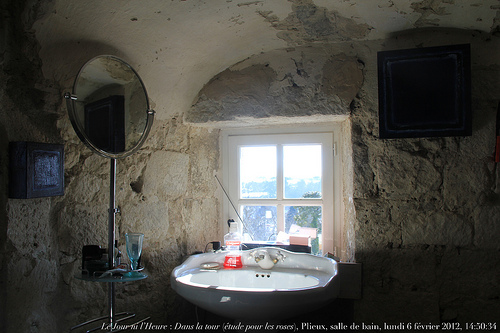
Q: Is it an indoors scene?
A: Yes, it is indoors.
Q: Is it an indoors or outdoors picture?
A: It is indoors.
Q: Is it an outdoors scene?
A: No, it is indoors.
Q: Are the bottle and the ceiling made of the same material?
A: No, the bottle is made of plastic and the ceiling is made of concrete.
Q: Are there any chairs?
A: No, there are no chairs.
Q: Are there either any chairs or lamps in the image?
A: No, there are no chairs or lamps.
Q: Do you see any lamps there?
A: No, there are no lamps.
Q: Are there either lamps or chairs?
A: No, there are no lamps or chairs.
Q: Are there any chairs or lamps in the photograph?
A: No, there are no lamps or chairs.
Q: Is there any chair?
A: No, there are no chairs.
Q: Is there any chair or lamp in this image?
A: No, there are no chairs or lamps.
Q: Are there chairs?
A: No, there are no chairs.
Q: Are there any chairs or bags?
A: No, there are no chairs or bags.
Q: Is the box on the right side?
A: Yes, the box is on the right of the image.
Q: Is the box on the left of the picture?
A: No, the box is on the right of the image.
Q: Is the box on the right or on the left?
A: The box is on the right of the image.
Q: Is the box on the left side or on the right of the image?
A: The box is on the right of the image.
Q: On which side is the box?
A: The box is on the right of the image.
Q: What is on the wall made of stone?
A: The box is on the wall.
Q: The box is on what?
A: The box is on the wall.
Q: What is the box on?
A: The box is on the wall.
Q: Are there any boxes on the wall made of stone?
A: Yes, there is a box on the wall.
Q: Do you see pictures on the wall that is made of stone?
A: No, there is a box on the wall.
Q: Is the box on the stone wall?
A: Yes, the box is on the wall.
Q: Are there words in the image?
A: Yes, there are words.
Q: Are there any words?
A: Yes, there are words.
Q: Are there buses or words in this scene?
A: Yes, there are words.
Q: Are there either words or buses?
A: Yes, there are words.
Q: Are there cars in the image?
A: No, there are no cars.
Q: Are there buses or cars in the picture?
A: No, there are no cars or buses.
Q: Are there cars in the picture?
A: No, there are no cars.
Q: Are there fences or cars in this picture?
A: No, there are no cars or fences.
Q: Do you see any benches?
A: No, there are no benches.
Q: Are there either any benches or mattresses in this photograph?
A: No, there are no benches or mattresses.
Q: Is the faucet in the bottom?
A: Yes, the faucet is in the bottom of the image.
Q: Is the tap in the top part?
A: No, the tap is in the bottom of the image.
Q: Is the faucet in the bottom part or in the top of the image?
A: The faucet is in the bottom of the image.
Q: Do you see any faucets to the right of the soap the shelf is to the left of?
A: Yes, there is a faucet to the right of the soap.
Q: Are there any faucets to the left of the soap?
A: No, the faucet is to the right of the soap.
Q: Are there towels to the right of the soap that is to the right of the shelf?
A: No, there is a faucet to the right of the soap.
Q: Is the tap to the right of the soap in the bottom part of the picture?
A: Yes, the tap is to the right of the soap.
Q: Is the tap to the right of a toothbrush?
A: No, the tap is to the right of the soap.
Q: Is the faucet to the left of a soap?
A: No, the faucet is to the right of a soap.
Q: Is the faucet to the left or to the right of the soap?
A: The faucet is to the right of the soap.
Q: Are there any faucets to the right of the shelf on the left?
A: Yes, there is a faucet to the right of the shelf.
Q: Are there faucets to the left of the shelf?
A: No, the faucet is to the right of the shelf.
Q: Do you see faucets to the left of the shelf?
A: No, the faucet is to the right of the shelf.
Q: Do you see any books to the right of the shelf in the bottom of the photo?
A: No, there is a faucet to the right of the shelf.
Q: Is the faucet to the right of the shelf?
A: Yes, the faucet is to the right of the shelf.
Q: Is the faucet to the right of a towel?
A: No, the faucet is to the right of the shelf.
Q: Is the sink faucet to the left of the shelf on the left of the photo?
A: No, the tap is to the right of the shelf.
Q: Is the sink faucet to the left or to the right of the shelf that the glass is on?
A: The tap is to the right of the shelf.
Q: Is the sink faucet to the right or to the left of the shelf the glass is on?
A: The tap is to the right of the shelf.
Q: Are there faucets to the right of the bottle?
A: Yes, there is a faucet to the right of the bottle.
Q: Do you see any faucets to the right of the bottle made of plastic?
A: Yes, there is a faucet to the right of the bottle.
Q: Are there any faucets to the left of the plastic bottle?
A: No, the faucet is to the right of the bottle.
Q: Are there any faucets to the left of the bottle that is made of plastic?
A: No, the faucet is to the right of the bottle.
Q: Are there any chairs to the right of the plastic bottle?
A: No, there is a faucet to the right of the bottle.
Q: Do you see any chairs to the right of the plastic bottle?
A: No, there is a faucet to the right of the bottle.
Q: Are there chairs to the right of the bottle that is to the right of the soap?
A: No, there is a faucet to the right of the bottle.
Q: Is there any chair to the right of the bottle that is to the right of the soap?
A: No, there is a faucet to the right of the bottle.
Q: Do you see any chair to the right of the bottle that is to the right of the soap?
A: No, there is a faucet to the right of the bottle.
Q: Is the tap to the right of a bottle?
A: Yes, the tap is to the right of a bottle.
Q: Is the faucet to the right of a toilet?
A: No, the faucet is to the right of a bottle.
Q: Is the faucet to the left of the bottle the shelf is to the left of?
A: No, the faucet is to the right of the bottle.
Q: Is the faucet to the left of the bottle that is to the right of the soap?
A: No, the faucet is to the right of the bottle.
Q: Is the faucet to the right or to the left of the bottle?
A: The faucet is to the right of the bottle.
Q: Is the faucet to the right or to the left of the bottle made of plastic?
A: The faucet is to the right of the bottle.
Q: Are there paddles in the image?
A: No, there are no paddles.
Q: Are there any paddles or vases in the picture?
A: No, there are no paddles or vases.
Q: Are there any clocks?
A: No, there are no clocks.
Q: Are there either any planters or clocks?
A: No, there are no clocks or planters.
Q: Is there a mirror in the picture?
A: Yes, there is a mirror.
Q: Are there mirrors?
A: Yes, there is a mirror.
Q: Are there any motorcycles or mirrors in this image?
A: Yes, there is a mirror.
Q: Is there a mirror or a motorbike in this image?
A: Yes, there is a mirror.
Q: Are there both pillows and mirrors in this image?
A: No, there is a mirror but no pillows.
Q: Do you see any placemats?
A: No, there are no placemats.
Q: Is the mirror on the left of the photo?
A: Yes, the mirror is on the left of the image.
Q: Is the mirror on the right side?
A: No, the mirror is on the left of the image.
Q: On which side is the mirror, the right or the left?
A: The mirror is on the left of the image.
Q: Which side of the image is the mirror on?
A: The mirror is on the left of the image.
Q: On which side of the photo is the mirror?
A: The mirror is on the left of the image.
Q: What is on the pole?
A: The mirror is on the pole.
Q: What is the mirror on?
A: The mirror is on the pole.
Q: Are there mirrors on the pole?
A: Yes, there is a mirror on the pole.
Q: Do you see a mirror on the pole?
A: Yes, there is a mirror on the pole.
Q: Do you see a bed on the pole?
A: No, there is a mirror on the pole.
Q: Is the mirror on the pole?
A: Yes, the mirror is on the pole.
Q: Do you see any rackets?
A: No, there are no rackets.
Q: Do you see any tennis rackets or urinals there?
A: No, there are no tennis rackets or urinals.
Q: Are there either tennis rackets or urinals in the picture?
A: No, there are no tennis rackets or urinals.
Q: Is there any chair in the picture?
A: No, there are no chairs.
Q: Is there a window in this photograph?
A: Yes, there is a window.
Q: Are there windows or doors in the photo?
A: Yes, there is a window.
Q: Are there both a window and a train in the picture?
A: No, there is a window but no trains.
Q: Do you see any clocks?
A: No, there are no clocks.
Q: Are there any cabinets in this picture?
A: Yes, there is a cabinet.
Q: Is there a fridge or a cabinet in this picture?
A: Yes, there is a cabinet.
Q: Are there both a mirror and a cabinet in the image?
A: Yes, there are both a cabinet and a mirror.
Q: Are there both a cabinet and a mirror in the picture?
A: Yes, there are both a cabinet and a mirror.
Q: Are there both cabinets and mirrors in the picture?
A: Yes, there are both a cabinet and a mirror.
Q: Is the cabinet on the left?
A: Yes, the cabinet is on the left of the image.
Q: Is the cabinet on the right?
A: No, the cabinet is on the left of the image.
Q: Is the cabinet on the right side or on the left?
A: The cabinet is on the left of the image.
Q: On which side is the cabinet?
A: The cabinet is on the left of the image.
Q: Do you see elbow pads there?
A: No, there are no elbow pads.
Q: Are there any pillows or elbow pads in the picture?
A: No, there are no elbow pads or pillows.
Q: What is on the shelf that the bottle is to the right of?
A: The glass is on the shelf.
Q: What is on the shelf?
A: The glass is on the shelf.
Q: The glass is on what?
A: The glass is on the shelf.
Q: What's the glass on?
A: The glass is on the shelf.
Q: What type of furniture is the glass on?
A: The glass is on the shelf.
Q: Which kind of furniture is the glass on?
A: The glass is on the shelf.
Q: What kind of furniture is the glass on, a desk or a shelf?
A: The glass is on a shelf.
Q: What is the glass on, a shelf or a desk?
A: The glass is on a shelf.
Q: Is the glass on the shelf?
A: Yes, the glass is on the shelf.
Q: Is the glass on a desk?
A: No, the glass is on the shelf.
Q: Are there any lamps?
A: No, there are no lamps.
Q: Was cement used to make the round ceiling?
A: Yes, the ceiling is made of cement.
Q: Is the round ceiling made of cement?
A: Yes, the ceiling is made of cement.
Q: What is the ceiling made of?
A: The ceiling is made of concrete.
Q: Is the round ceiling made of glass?
A: No, the ceiling is made of cement.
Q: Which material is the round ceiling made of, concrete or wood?
A: The ceiling is made of concrete.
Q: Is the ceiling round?
A: Yes, the ceiling is round.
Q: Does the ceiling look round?
A: Yes, the ceiling is round.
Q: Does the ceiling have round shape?
A: Yes, the ceiling is round.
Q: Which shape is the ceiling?
A: The ceiling is round.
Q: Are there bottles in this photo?
A: Yes, there is a bottle.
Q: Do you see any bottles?
A: Yes, there is a bottle.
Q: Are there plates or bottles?
A: Yes, there is a bottle.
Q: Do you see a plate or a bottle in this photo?
A: Yes, there is a bottle.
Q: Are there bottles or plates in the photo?
A: Yes, there is a bottle.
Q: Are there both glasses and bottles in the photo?
A: Yes, there are both a bottle and glasses.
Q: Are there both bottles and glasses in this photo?
A: Yes, there are both a bottle and glasses.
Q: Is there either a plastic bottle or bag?
A: Yes, there is a plastic bottle.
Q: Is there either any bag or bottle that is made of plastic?
A: Yes, the bottle is made of plastic.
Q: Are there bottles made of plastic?
A: Yes, there is a bottle that is made of plastic.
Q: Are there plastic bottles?
A: Yes, there is a bottle that is made of plastic.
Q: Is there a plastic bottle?
A: Yes, there is a bottle that is made of plastic.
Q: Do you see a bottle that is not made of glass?
A: Yes, there is a bottle that is made of plastic.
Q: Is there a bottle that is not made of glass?
A: Yes, there is a bottle that is made of plastic.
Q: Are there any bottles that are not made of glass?
A: Yes, there is a bottle that is made of plastic.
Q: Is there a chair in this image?
A: No, there are no chairs.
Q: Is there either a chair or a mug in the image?
A: No, there are no chairs or mugs.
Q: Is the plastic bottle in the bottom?
A: Yes, the bottle is in the bottom of the image.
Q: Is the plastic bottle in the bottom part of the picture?
A: Yes, the bottle is in the bottom of the image.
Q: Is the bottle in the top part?
A: No, the bottle is in the bottom of the image.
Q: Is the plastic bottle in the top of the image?
A: No, the bottle is in the bottom of the image.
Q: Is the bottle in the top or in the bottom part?
A: The bottle is in the bottom of the image.